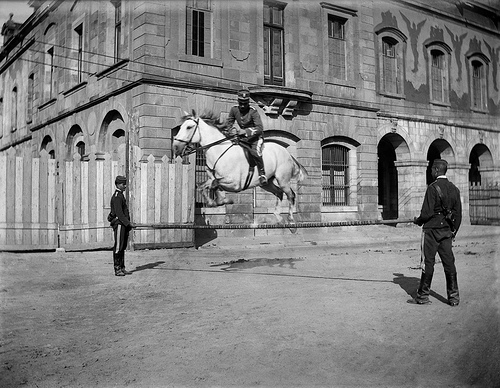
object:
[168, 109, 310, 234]
horse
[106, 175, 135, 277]
man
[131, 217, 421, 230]
pole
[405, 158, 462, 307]
man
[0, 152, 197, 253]
fence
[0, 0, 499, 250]
building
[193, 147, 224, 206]
bars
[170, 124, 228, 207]
window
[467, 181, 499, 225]
fence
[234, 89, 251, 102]
hat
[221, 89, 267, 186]
man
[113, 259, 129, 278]
foot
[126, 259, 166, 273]
shadow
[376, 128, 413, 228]
archway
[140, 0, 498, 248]
facade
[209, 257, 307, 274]
shadow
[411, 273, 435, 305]
boots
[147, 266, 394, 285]
shadow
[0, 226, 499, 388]
ground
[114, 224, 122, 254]
stripe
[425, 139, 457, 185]
opening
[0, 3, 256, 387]
right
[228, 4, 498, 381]
left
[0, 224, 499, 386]
road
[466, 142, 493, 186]
doorway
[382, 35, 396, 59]
window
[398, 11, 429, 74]
angel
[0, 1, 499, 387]
photo